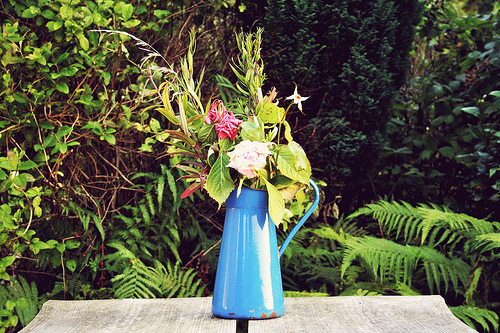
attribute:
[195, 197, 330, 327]
pitcher — blue, metal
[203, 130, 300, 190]
pink peony — large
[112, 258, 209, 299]
fern — green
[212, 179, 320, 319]
can — blue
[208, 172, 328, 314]
pitcher — blue, antique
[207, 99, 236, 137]
flower — hot pink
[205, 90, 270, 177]
flowers — wilted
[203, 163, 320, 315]
can — blue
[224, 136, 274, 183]
flower — light pink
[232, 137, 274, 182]
flowers — pink 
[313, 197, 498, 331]
fern plant — green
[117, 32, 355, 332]
vase — pretty, blue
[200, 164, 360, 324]
vase — rusty 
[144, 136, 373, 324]
can — blue 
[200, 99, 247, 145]
flower — pink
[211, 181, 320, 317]
pitcher — blue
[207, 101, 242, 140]
flower — red 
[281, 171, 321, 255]
handle — blue 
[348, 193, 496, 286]
ferns — wild